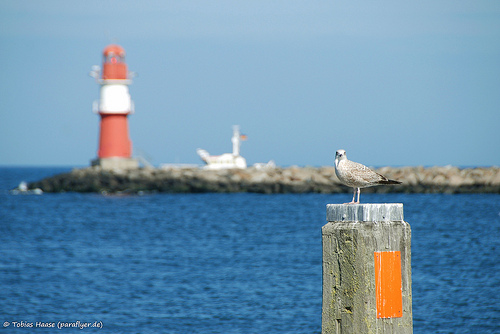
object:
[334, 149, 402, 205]
seagull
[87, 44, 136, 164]
lighthouse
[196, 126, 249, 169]
ship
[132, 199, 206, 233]
wave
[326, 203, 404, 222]
cap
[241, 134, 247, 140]
flag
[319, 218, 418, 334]
pole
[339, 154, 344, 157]
beak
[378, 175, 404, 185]
tail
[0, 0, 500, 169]
sky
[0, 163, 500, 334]
ocean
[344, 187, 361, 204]
leg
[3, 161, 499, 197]
island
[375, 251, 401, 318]
paint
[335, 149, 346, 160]
head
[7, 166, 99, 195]
stone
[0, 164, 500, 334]
lagoon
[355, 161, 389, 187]
wing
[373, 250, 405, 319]
sign